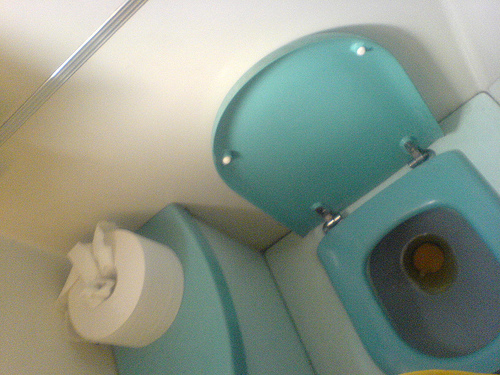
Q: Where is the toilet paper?
A: Next to the toilet.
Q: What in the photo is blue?
A: The toilet seat.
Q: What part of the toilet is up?
A: The lid.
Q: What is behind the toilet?
A: A wall.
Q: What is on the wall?
A: A metal trim.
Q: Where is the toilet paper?
A: On a blue and white box.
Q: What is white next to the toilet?
A: Toilet paper.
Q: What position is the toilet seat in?
A: The up position.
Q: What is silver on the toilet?
A: The hinges.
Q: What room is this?
A: A bathroom.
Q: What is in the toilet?
A: Water.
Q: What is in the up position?
A: The toilet seat.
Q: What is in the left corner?
A: Toilet paper.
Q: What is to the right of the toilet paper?
A: A toilet.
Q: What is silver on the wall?
A: Trim.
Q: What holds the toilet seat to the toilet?
A: Hinges.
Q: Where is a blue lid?
A: Over a toilet.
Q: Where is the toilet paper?
A: On a box.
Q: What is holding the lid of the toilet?
A: Two hinges.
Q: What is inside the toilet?
A: Excrement.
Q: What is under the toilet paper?
A: A shelf.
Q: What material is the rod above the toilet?
A: Metal.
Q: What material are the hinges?
A: Metal.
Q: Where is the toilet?
A: In a bathroom.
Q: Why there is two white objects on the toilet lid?
A: For support.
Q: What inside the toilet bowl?
A: Urine.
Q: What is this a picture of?
A: Toilet.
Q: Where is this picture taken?
A: Bathroom.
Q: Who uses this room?
A: Whole family.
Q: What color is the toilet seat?
A: Blue.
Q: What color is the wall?
A: White.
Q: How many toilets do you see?
A: 1.